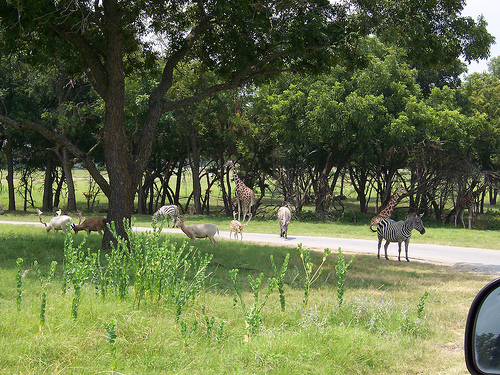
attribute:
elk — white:
[68, 216, 103, 231]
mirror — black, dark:
[457, 273, 494, 373]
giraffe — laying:
[212, 147, 269, 229]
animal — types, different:
[365, 207, 429, 261]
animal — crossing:
[273, 201, 293, 238]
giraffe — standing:
[228, 166, 255, 225]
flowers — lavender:
[222, 269, 389, 373]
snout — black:
[419, 227, 429, 238]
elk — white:
[161, 188, 311, 248]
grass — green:
[326, 294, 393, 364]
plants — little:
[263, 261, 348, 308]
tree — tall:
[39, 8, 204, 277]